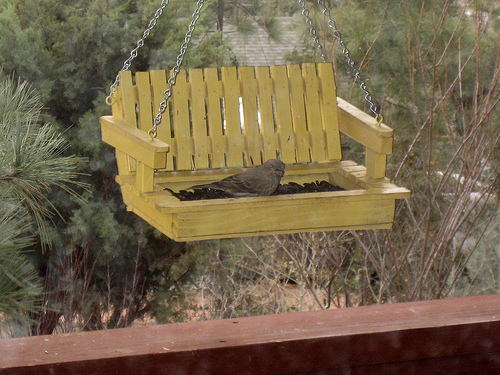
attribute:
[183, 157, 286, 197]
bird — small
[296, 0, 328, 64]
chain — metal, small, silver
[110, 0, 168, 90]
chain — small, silver, metal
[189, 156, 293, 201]
bird — small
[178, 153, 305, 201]
bird — feathered, small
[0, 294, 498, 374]
rail — wooden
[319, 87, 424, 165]
armrest — wooden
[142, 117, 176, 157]
hook — eye hook, small, yellow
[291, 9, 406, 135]
chain — Grey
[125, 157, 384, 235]
bird feeder — miniature bench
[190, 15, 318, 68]
roof — sloping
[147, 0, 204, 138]
chain — small, silver, metal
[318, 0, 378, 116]
chain — small, silver, metal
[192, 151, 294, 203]
bird — little, light brown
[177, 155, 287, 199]
bird — small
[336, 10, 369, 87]
horse — metal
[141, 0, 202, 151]
chain — grey, metal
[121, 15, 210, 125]
chains — grey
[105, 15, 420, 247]
bench — Yellow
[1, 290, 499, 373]
wall — low, wooden, red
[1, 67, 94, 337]
bough — pine tree's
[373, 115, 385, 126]
eye hook — yellow, small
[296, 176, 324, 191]
food — bird food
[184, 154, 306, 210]
bird — small, brown, grey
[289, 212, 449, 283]
branches — bare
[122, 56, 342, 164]
back — wooden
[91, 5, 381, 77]
metal chain — grey, metal chain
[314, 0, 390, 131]
metal chain — silver, small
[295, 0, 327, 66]
metal chain — small, silver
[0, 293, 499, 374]
wooden board — maroon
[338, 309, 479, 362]
painted board — brown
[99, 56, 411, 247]
bird feeder — miniature bench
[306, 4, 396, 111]
chain — grey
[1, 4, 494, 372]
area — rural